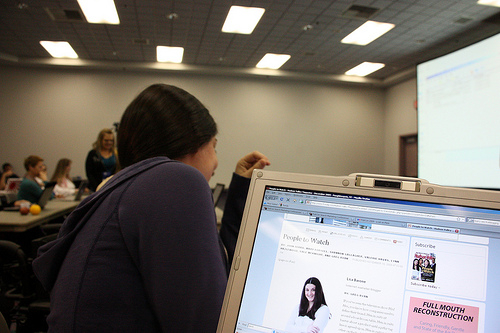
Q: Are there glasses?
A: No, there are no glasses.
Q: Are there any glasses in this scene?
A: No, there are no glasses.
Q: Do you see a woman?
A: Yes, there is a woman.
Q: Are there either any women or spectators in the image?
A: Yes, there is a woman.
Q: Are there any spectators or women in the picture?
A: Yes, there is a woman.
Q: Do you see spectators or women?
A: Yes, there is a woman.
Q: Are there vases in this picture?
A: No, there are no vases.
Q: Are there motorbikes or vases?
A: No, there are no vases or motorbikes.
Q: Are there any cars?
A: No, there are no cars.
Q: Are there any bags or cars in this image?
A: No, there are no cars or bags.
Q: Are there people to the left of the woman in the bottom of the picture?
A: Yes, there are people to the left of the woman.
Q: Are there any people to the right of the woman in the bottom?
A: No, the people are to the left of the woman.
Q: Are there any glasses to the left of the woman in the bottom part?
A: No, there are people to the left of the woman.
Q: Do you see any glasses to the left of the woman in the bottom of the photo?
A: No, there are people to the left of the woman.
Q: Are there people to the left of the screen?
A: Yes, there are people to the left of the screen.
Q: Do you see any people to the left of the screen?
A: Yes, there are people to the left of the screen.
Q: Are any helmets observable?
A: No, there are no helmets.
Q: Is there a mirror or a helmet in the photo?
A: No, there are no helmets or mirrors.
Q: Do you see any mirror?
A: No, there are no mirrors.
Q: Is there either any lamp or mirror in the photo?
A: No, there are no mirrors or lamps.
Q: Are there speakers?
A: No, there are no speakers.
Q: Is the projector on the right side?
A: Yes, the projector is on the right of the image.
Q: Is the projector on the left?
A: No, the projector is on the right of the image.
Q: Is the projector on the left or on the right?
A: The projector is on the right of the image.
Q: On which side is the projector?
A: The projector is on the right of the image.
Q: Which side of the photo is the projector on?
A: The projector is on the right of the image.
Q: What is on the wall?
A: The projector is on the wall.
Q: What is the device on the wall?
A: The device is a projector.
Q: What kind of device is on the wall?
A: The device is a projector.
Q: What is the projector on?
A: The projector is on the wall.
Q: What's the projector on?
A: The projector is on the wall.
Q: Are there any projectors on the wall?
A: Yes, there is a projector on the wall.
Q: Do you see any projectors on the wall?
A: Yes, there is a projector on the wall.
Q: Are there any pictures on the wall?
A: No, there is a projector on the wall.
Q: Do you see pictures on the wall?
A: No, there is a projector on the wall.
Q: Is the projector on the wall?
A: Yes, the projector is on the wall.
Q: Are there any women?
A: Yes, there is a woman.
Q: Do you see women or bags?
A: Yes, there is a woman.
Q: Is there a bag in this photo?
A: No, there are no bags.